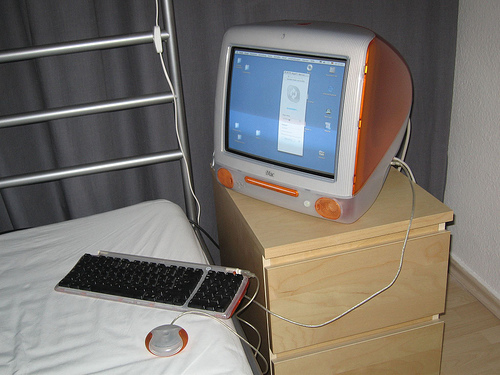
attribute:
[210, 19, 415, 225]
monitor — colored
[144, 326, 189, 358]
mouse — colored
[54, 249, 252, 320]
keyboard — colored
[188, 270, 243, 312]
pad — numbered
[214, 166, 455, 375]
nightstand — wooden, brown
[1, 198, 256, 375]
mattress — white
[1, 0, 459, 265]
curtains — gray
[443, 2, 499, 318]
wall — white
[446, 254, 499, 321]
baseboard — tan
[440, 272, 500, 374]
floor — wooden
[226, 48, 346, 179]
screen — blue, on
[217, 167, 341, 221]
speakers — orange